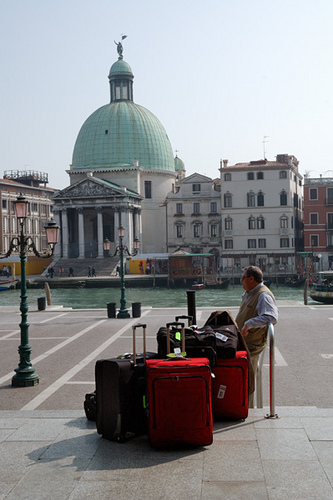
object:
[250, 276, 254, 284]
ear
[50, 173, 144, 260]
building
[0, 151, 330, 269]
background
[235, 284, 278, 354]
top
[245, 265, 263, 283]
hair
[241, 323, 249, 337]
hand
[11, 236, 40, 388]
green pole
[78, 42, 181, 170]
roof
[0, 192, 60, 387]
light pole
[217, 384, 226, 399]
tag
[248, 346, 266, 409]
pants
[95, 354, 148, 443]
black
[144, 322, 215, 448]
bag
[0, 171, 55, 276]
building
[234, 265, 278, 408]
body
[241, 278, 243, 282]
nose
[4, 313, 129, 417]
line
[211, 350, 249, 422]
bag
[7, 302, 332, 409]
street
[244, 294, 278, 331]
arm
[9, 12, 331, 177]
sky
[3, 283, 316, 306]
water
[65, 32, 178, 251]
building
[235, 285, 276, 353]
sweater vest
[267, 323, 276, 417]
metal pole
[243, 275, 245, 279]
eye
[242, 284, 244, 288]
mouth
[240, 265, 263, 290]
head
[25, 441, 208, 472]
shadow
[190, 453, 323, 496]
ground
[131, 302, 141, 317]
container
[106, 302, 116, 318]
container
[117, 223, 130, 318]
pole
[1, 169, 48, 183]
balcony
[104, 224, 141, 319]
street lamp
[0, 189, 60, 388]
street lamp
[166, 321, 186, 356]
handle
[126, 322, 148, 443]
luggage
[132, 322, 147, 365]
handle